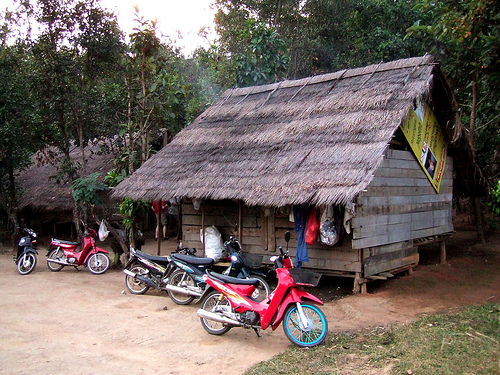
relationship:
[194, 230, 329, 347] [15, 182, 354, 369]
motorbike parked outside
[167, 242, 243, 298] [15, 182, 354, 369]
scooter parked outside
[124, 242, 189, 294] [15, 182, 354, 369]
scooter parked outside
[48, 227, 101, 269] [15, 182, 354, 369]
scooter parked outside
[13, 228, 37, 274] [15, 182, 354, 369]
scooter parked outside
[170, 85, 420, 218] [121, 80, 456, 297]
roof on building